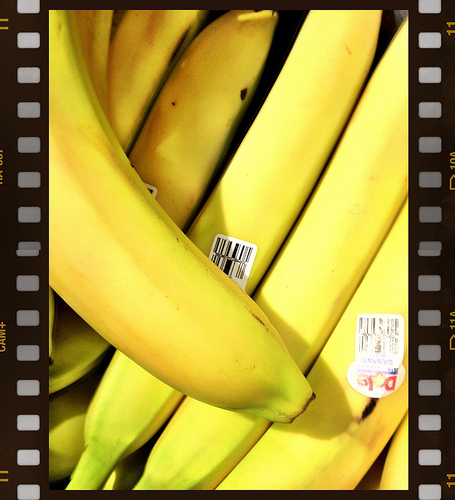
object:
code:
[354, 317, 403, 373]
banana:
[62, 8, 382, 490]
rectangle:
[16, 31, 40, 47]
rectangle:
[16, 100, 41, 118]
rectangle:
[16, 169, 41, 187]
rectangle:
[417, 66, 443, 84]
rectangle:
[418, 134, 442, 152]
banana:
[67, 9, 113, 114]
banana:
[105, 9, 206, 152]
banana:
[131, 19, 407, 488]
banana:
[46, 6, 282, 404]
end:
[264, 363, 317, 425]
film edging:
[409, 0, 454, 498]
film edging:
[0, 0, 50, 497]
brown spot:
[235, 85, 250, 103]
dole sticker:
[344, 353, 407, 399]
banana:
[126, 8, 278, 231]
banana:
[54, 15, 323, 429]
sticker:
[206, 233, 258, 289]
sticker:
[135, 182, 158, 200]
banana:
[194, 201, 410, 492]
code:
[208, 235, 254, 280]